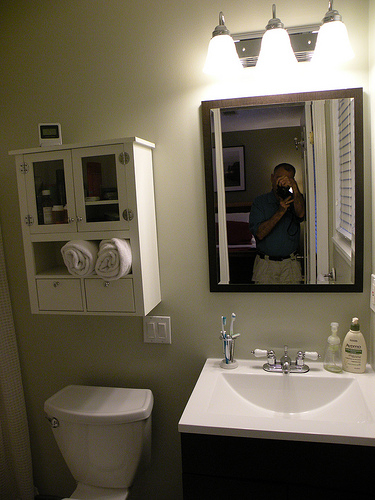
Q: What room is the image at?
A: It is at the bathroom.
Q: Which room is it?
A: It is a bathroom.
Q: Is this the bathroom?
A: Yes, it is the bathroom.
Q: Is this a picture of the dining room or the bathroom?
A: It is showing the bathroom.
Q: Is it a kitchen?
A: No, it is a bathroom.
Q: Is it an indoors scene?
A: Yes, it is indoors.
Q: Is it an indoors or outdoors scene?
A: It is indoors.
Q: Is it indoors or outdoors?
A: It is indoors.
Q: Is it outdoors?
A: No, it is indoors.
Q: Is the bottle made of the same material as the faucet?
A: No, the bottle is made of plastic and the faucet is made of metal.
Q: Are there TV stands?
A: No, there are no TV stands.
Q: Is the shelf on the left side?
A: Yes, the shelf is on the left of the image.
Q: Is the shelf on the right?
A: No, the shelf is on the left of the image.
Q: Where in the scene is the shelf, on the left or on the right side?
A: The shelf is on the left of the image.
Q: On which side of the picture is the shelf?
A: The shelf is on the left of the image.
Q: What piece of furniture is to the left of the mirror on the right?
A: The piece of furniture is a shelf.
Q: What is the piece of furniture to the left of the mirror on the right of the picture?
A: The piece of furniture is a shelf.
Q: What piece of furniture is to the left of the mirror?
A: The piece of furniture is a shelf.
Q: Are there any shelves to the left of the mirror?
A: Yes, there is a shelf to the left of the mirror.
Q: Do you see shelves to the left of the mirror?
A: Yes, there is a shelf to the left of the mirror.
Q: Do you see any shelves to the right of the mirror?
A: No, the shelf is to the left of the mirror.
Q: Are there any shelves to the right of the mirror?
A: No, the shelf is to the left of the mirror.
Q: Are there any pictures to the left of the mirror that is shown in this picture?
A: No, there is a shelf to the left of the mirror.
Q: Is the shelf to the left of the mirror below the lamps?
A: Yes, the shelf is to the left of the mirror.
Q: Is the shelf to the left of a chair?
A: No, the shelf is to the left of the mirror.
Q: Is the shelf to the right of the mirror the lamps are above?
A: No, the shelf is to the left of the mirror.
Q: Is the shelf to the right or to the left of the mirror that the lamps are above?
A: The shelf is to the left of the mirror.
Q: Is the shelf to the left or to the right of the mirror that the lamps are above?
A: The shelf is to the left of the mirror.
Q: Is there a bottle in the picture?
A: Yes, there is a bottle.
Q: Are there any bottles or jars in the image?
A: Yes, there is a bottle.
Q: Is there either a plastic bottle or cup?
A: Yes, there is a plastic bottle.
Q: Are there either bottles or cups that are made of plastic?
A: Yes, the bottle is made of plastic.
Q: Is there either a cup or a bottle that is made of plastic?
A: Yes, the bottle is made of plastic.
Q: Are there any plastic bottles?
A: Yes, there is a bottle that is made of plastic.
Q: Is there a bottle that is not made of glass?
A: Yes, there is a bottle that is made of plastic.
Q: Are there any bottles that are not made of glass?
A: Yes, there is a bottle that is made of plastic.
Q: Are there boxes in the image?
A: No, there are no boxes.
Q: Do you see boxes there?
A: No, there are no boxes.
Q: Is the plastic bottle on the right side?
A: Yes, the bottle is on the right of the image.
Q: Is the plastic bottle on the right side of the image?
A: Yes, the bottle is on the right of the image.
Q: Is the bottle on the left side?
A: No, the bottle is on the right of the image.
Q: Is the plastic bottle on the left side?
A: No, the bottle is on the right of the image.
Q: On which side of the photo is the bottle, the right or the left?
A: The bottle is on the right of the image.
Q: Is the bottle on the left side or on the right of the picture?
A: The bottle is on the right of the image.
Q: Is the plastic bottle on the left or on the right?
A: The bottle is on the right of the image.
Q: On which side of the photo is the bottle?
A: The bottle is on the right of the image.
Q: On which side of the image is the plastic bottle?
A: The bottle is on the right of the image.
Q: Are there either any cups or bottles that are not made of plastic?
A: No, there is a bottle but it is made of plastic.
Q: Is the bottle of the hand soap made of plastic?
A: Yes, the bottle is made of plastic.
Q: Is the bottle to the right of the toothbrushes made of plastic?
A: Yes, the bottle is made of plastic.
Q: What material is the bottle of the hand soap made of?
A: The bottle is made of plastic.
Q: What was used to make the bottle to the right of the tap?
A: The bottle is made of plastic.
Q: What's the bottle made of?
A: The bottle is made of plastic.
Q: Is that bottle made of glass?
A: No, the bottle is made of plastic.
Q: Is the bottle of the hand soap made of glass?
A: No, the bottle is made of plastic.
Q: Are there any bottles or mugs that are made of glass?
A: No, there is a bottle but it is made of plastic.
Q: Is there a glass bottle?
A: No, there is a bottle but it is made of plastic.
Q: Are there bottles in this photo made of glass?
A: No, there is a bottle but it is made of plastic.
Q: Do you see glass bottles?
A: No, there is a bottle but it is made of plastic.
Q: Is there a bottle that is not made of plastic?
A: No, there is a bottle but it is made of plastic.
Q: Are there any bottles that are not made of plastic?
A: No, there is a bottle but it is made of plastic.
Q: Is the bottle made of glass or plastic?
A: The bottle is made of plastic.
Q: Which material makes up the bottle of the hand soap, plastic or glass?
A: The bottle is made of plastic.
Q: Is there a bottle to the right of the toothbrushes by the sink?
A: Yes, there is a bottle to the right of the toothbrushes.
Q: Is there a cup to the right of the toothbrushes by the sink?
A: No, there is a bottle to the right of the toothbrushes.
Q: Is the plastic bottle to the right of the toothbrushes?
A: Yes, the bottle is to the right of the toothbrushes.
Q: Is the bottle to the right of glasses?
A: No, the bottle is to the right of the toothbrushes.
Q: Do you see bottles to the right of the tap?
A: Yes, there is a bottle to the right of the tap.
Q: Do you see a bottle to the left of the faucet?
A: No, the bottle is to the right of the faucet.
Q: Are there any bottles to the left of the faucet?
A: No, the bottle is to the right of the faucet.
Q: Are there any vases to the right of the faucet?
A: No, there is a bottle to the right of the faucet.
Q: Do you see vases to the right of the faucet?
A: No, there is a bottle to the right of the faucet.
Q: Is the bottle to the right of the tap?
A: Yes, the bottle is to the right of the tap.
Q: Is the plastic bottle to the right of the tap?
A: Yes, the bottle is to the right of the tap.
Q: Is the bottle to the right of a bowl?
A: No, the bottle is to the right of the tap.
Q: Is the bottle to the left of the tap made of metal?
A: No, the bottle is to the right of the faucet.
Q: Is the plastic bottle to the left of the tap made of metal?
A: No, the bottle is to the right of the faucet.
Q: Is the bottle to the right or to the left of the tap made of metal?
A: The bottle is to the right of the tap.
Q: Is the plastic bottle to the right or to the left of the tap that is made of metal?
A: The bottle is to the right of the tap.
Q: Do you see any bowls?
A: No, there are no bowls.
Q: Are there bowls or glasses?
A: No, there are no bowls or glasses.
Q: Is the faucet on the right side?
A: Yes, the faucet is on the right of the image.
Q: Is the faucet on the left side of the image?
A: No, the faucet is on the right of the image.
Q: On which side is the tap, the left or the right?
A: The tap is on the right of the image.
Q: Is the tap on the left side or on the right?
A: The tap is on the right of the image.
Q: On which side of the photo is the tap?
A: The tap is on the right of the image.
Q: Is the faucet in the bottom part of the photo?
A: Yes, the faucet is in the bottom of the image.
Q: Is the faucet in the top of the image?
A: No, the faucet is in the bottom of the image.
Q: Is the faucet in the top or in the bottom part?
A: The faucet is in the bottom of the image.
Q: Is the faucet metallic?
A: Yes, the faucet is metallic.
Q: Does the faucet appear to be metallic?
A: Yes, the faucet is metallic.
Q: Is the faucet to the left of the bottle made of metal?
A: Yes, the tap is made of metal.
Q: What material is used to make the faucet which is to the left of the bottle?
A: The faucet is made of metal.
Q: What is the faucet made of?
A: The faucet is made of metal.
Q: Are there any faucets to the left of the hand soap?
A: Yes, there is a faucet to the left of the hand soap.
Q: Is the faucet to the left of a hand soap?
A: Yes, the faucet is to the left of a hand soap.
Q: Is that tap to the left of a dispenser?
A: No, the tap is to the left of a hand soap.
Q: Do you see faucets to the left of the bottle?
A: Yes, there is a faucet to the left of the bottle.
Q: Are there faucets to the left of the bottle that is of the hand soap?
A: Yes, there is a faucet to the left of the bottle.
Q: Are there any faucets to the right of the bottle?
A: No, the faucet is to the left of the bottle.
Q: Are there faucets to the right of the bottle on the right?
A: No, the faucet is to the left of the bottle.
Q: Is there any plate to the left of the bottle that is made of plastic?
A: No, there is a faucet to the left of the bottle.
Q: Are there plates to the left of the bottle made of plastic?
A: No, there is a faucet to the left of the bottle.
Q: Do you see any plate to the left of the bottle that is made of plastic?
A: No, there is a faucet to the left of the bottle.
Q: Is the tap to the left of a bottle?
A: Yes, the tap is to the left of a bottle.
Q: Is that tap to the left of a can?
A: No, the tap is to the left of a bottle.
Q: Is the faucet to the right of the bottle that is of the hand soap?
A: No, the faucet is to the left of the bottle.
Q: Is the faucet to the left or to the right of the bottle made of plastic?
A: The faucet is to the left of the bottle.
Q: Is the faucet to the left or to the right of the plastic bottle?
A: The faucet is to the left of the bottle.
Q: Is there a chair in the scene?
A: No, there are no chairs.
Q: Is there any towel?
A: Yes, there is a towel.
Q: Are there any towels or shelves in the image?
A: Yes, there is a towel.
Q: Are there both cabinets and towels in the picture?
A: Yes, there are both a towel and a cabinet.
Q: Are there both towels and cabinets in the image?
A: Yes, there are both a towel and a cabinet.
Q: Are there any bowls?
A: No, there are no bowls.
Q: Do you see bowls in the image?
A: No, there are no bowls.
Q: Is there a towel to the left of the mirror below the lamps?
A: Yes, there is a towel to the left of the mirror.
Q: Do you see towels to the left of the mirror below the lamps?
A: Yes, there is a towel to the left of the mirror.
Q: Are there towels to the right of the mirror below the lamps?
A: No, the towel is to the left of the mirror.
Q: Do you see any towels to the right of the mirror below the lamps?
A: No, the towel is to the left of the mirror.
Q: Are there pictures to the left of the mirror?
A: No, there is a towel to the left of the mirror.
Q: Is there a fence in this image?
A: No, there are no fences.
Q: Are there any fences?
A: No, there are no fences.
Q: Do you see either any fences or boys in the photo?
A: No, there are no fences or boys.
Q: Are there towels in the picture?
A: Yes, there is a towel.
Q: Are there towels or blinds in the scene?
A: Yes, there is a towel.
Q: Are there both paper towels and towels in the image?
A: No, there is a towel but no paper towels.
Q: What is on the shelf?
A: The towel is on the shelf.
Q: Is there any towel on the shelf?
A: Yes, there is a towel on the shelf.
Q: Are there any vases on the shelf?
A: No, there is a towel on the shelf.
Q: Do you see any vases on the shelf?
A: No, there is a towel on the shelf.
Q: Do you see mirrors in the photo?
A: Yes, there is a mirror.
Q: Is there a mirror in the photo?
A: Yes, there is a mirror.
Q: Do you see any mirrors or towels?
A: Yes, there is a mirror.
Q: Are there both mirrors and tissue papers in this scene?
A: No, there is a mirror but no tissues.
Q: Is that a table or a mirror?
A: That is a mirror.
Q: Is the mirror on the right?
A: Yes, the mirror is on the right of the image.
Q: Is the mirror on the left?
A: No, the mirror is on the right of the image.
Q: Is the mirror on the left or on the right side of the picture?
A: The mirror is on the right of the image.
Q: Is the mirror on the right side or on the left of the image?
A: The mirror is on the right of the image.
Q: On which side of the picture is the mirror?
A: The mirror is on the right of the image.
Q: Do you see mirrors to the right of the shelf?
A: Yes, there is a mirror to the right of the shelf.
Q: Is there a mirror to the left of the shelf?
A: No, the mirror is to the right of the shelf.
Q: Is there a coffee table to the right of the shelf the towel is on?
A: No, there is a mirror to the right of the shelf.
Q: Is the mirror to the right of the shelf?
A: Yes, the mirror is to the right of the shelf.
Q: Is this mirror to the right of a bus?
A: No, the mirror is to the right of the shelf.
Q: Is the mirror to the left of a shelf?
A: No, the mirror is to the right of a shelf.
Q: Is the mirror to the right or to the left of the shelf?
A: The mirror is to the right of the shelf.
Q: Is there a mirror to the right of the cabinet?
A: Yes, there is a mirror to the right of the cabinet.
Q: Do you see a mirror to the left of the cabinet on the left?
A: No, the mirror is to the right of the cabinet.